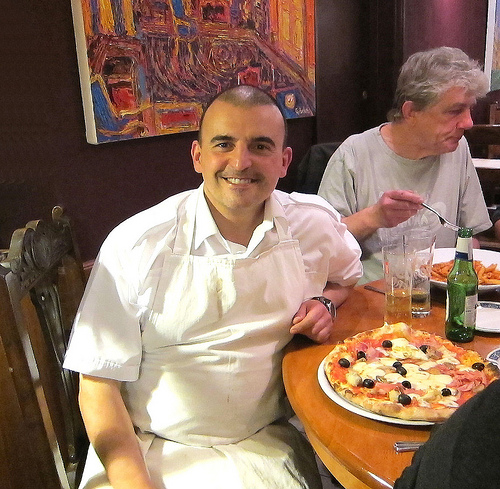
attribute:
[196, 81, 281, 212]
head — shaved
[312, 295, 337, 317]
watch — bulky, silver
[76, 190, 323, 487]
apron — white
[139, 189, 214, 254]
strings — apron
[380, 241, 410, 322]
glass — half filled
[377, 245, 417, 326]
glass — clear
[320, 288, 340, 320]
watch — man's, wrist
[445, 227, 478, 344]
bottle — empty beer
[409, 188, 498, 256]
spoon — silver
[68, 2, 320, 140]
painting — colorful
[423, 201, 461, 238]
fork — in man's hand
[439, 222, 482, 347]
bottle — empty, beer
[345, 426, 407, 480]
table — top, dinning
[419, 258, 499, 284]
pasta — red sauce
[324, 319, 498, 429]
pizza — tasty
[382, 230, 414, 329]
glass — tall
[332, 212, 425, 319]
glass — clear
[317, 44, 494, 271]
man — holding a fork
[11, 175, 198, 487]
chair — intricately carved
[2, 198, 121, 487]
chair — dining, back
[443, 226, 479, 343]
wine bottle — white, tall green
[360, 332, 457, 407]
pizza — part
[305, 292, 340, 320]
watch — man's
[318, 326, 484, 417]
plate — pizza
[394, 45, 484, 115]
hair — man